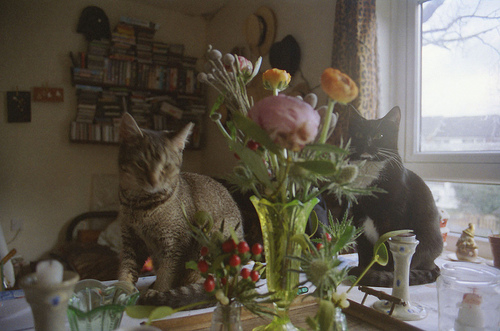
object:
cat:
[116, 111, 245, 309]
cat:
[340, 103, 444, 288]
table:
[0, 248, 499, 331]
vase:
[248, 195, 320, 331]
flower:
[247, 95, 321, 152]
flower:
[319, 67, 359, 105]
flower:
[260, 68, 292, 94]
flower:
[197, 43, 262, 87]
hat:
[268, 34, 301, 77]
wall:
[200, 0, 351, 189]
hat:
[246, 3, 276, 57]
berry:
[204, 275, 216, 292]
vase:
[207, 298, 242, 331]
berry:
[250, 270, 259, 281]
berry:
[252, 243, 262, 255]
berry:
[230, 255, 240, 267]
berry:
[198, 262, 208, 272]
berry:
[223, 238, 237, 253]